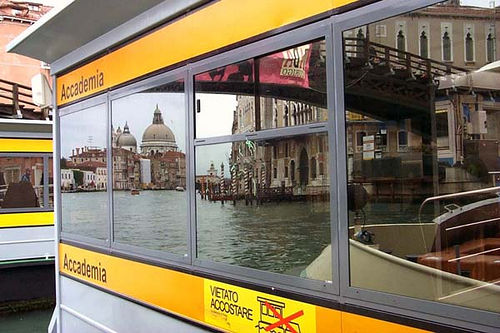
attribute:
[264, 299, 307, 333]
x — red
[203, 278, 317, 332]
sign — red, yellow, black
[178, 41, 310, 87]
banner — black, yellow, red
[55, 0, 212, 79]
stripe — black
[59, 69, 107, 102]
writing — black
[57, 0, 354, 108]
background — yellow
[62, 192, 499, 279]
water — rippled, calm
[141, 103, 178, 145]
dome — large, round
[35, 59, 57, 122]
person — standing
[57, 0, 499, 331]
window — transparent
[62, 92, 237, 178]
sky — blue